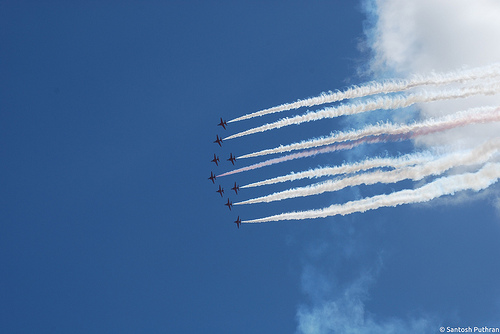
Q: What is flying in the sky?
A: Planes.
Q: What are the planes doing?
A: Flying.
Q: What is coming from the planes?
A: Smoke.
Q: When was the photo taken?
A: The morning.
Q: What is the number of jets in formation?
A: Nine.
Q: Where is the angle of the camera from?
A: Below.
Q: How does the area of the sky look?
A: Cloudy.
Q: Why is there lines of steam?
A: Jet trails.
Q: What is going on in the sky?
A: Air show.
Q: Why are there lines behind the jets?
A: Smoke trails.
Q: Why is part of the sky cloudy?
A: Jet smoke.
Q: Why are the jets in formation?
A: Air show.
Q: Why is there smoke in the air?
A: Jet trails.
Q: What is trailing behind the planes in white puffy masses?
A: Smoke.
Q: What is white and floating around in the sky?
A: Cloud.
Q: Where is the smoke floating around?
A: Sky.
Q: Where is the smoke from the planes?
A: In the sky.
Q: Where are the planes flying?
A: In the sky.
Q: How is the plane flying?
A: Wings.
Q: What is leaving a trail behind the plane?
A: Smoke.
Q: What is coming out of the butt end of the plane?
A: Smoke trail.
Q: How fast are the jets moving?
A: Quickly.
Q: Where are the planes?
A: In the sky.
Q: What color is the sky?
A: Blue and white.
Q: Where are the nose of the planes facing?
A: Towards the left side of the picture.